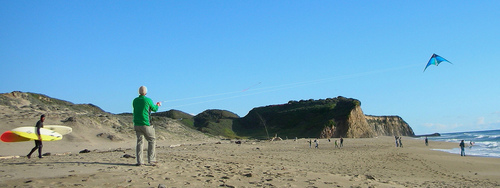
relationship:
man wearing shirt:
[125, 78, 172, 173] [130, 96, 172, 126]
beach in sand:
[0, 135, 499, 187] [1, 136, 498, 186]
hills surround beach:
[0, 85, 415, 138] [2, 134, 499, 186]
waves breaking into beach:
[422, 122, 499, 160] [0, 129, 499, 184]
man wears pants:
[125, 78, 172, 173] [136, 125, 157, 165]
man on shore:
[459, 140, 466, 157] [429, 134, 498, 161]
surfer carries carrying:
[29, 112, 47, 157] [0, 124, 72, 142]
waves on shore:
[417, 129, 500, 157] [401, 140, 463, 183]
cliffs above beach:
[0, 90, 415, 144] [2, 134, 499, 186]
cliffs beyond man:
[1, 86, 417, 139] [127, 79, 165, 166]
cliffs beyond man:
[1, 86, 417, 139] [25, 110, 48, 161]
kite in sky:
[425, 50, 446, 69] [207, 11, 339, 79]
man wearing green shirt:
[125, 78, 172, 173] [129, 95, 160, 123]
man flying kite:
[125, 78, 172, 173] [418, 42, 452, 74]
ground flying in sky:
[338, 112, 350, 162] [2, 0, 498, 130]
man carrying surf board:
[27, 115, 47, 159] [1, 124, 71, 140]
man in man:
[27, 115, 47, 159] [27, 115, 47, 159]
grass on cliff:
[284, 96, 363, 106] [279, 95, 417, 137]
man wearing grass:
[125, 78, 172, 173] [146, 96, 363, 141]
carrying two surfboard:
[14, 121, 82, 141] [8, 127, 63, 142]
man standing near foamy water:
[453, 128, 473, 156] [359, 98, 490, 188]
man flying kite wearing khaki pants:
[33, 102, 57, 158] [132, 124, 164, 188]